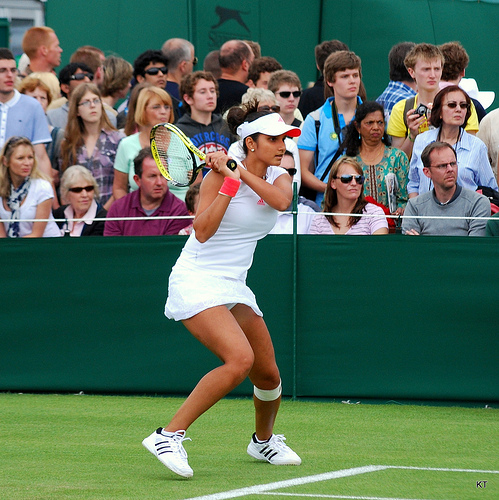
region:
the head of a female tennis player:
[235, 111, 296, 173]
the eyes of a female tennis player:
[255, 129, 281, 145]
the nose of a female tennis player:
[271, 134, 289, 151]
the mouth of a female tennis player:
[266, 146, 296, 168]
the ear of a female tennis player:
[238, 133, 263, 158]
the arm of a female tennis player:
[192, 163, 236, 232]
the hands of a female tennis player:
[206, 150, 239, 184]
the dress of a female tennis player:
[212, 195, 281, 324]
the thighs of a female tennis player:
[192, 306, 287, 377]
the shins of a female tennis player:
[147, 352, 293, 446]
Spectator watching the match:
[398, 140, 492, 236]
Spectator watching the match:
[309, 149, 385, 236]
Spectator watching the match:
[107, 142, 192, 233]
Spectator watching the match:
[42, 159, 105, 233]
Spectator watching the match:
[1, 138, 55, 233]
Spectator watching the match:
[411, 79, 495, 143]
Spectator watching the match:
[346, 100, 400, 175]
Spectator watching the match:
[318, 46, 374, 111]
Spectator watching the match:
[400, 42, 451, 108]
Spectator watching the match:
[175, 73, 226, 138]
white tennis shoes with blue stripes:
[135, 415, 303, 481]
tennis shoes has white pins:
[133, 419, 307, 478]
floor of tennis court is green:
[1, 388, 498, 497]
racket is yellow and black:
[142, 114, 241, 192]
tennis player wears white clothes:
[135, 85, 321, 484]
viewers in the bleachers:
[1, 28, 496, 240]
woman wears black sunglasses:
[312, 154, 389, 238]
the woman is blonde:
[110, 81, 206, 188]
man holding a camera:
[383, 38, 447, 134]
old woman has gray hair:
[41, 164, 110, 235]